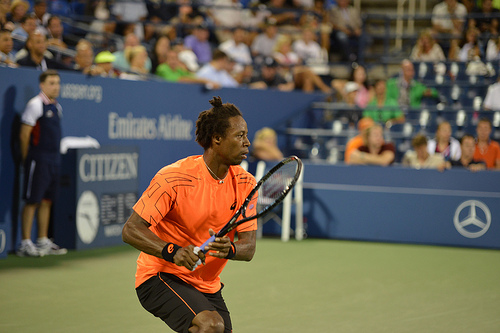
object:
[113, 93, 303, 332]
tennis player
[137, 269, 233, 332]
shorts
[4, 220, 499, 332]
court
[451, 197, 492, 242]
sponsor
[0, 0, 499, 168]
audience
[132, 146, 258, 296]
shirt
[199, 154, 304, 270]
racket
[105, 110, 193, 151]
sponsor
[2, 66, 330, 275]
wall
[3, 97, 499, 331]
tennis match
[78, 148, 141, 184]
sponsor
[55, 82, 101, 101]
logo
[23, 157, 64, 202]
shorts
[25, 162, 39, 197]
stripe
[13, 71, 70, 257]
man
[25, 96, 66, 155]
shirt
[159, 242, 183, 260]
wristband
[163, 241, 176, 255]
design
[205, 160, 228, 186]
necklace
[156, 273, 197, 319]
stripe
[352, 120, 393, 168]
spectator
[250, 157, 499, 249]
wall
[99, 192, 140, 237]
clock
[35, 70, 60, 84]
hair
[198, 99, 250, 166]
head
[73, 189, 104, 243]
clock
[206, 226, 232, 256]
left hand